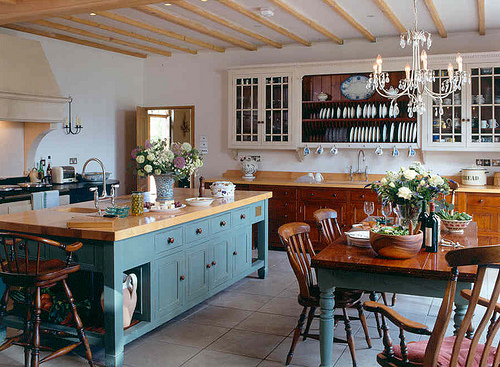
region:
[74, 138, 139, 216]
Silver metal kitchen faucet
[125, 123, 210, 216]
Purple and white flowers in vase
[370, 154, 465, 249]
White flowers in vase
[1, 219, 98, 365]
Dark brown wooden kitchen stool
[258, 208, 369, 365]
Brown wooden dining room chair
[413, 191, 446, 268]
Large bottle of wine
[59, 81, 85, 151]
Metal wall light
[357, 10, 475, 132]
White metal and glass chandelier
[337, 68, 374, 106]
Decorative blue and white plate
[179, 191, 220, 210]
White ceramic plate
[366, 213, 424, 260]
wooden salad tongs in teak wood salad bowl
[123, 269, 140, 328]
white ceramic pitcher inside blue kitchen island cupboard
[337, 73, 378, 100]
blue & white delftpottery serving plate displayed in built-in china cabinet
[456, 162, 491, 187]
breadmaker labeled 'BREAD' in 70s or 80s font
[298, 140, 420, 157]
several matching china cups with turquoise pattern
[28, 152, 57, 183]
small group of bottled cabinets beside built-in oven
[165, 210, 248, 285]
round dark wood drawer pulls on cupboard that match tabletop & chairs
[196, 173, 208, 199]
dark wood pepper grinder atop butcher block top of cupboard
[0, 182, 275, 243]
top of kitchen island cupboard is butcher block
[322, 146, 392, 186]
sink is clean & dirty dish free! yow!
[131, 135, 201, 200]
a vase full of flowers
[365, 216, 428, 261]
a bowl full of salad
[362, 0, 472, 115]
a hanging chandelier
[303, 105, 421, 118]
a row of dishes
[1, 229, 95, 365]
a high wooden chair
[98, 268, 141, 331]
a white and tan earthenware pitcher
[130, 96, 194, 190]
the door is open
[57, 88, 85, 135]
a candle sconce hanging on the wall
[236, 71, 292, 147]
glass paneled cabinets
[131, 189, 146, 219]
a jar of green olives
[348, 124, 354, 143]
round dinner plate on its edge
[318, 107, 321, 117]
round dinner plate on its edge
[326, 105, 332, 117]
round dinner plate on its edge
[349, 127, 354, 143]
round white dinner plate on its edge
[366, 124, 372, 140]
round white dinner plate on its edge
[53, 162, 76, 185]
white and silver toaster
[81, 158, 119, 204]
curved metal faucet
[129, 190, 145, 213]
jar of green olives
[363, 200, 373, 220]
empty wine glass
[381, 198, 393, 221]
empty wine glass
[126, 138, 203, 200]
vase with flowers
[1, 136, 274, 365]
vase is on kitchen island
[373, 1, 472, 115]
white chandelier light hanging from ceiling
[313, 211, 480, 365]
table is dark wood and light blue paint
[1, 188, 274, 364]
island is wood and light blue paint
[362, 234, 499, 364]
chair is wood with pink pad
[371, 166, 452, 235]
vase with flowers on table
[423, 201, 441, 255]
bottle of red wine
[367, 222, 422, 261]
wood salad bowl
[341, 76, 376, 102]
blue and white oval plate